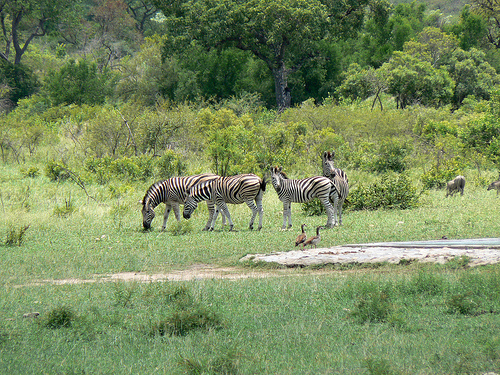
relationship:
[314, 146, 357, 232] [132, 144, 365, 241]
zebra in group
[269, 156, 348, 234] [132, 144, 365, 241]
zebra in group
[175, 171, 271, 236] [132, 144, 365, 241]
zebra in group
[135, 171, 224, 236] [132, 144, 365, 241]
zebra in group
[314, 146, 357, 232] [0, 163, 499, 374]
zebra in grass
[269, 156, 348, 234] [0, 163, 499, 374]
zebra in grass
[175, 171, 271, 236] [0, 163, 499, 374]
zebra in grass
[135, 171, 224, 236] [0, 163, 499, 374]
zebra in grass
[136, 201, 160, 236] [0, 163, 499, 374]
head touching grass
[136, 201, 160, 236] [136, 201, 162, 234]
head angled down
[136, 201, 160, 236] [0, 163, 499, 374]
head angled torward grass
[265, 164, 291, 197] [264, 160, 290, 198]
head turned to side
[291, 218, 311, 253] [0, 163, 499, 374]
bird in grass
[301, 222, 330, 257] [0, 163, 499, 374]
bird in grass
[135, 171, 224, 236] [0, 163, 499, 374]
zebra grazing grass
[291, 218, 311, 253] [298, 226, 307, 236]
bird has neck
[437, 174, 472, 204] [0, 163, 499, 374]
animal in grass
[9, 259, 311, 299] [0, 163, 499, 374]
sand beside grass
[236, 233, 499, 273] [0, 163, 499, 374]
pavement beside grass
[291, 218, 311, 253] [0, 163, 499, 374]
bird walking in grass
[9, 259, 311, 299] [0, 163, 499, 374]
sand in grass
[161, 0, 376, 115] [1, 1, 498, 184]
tree in brush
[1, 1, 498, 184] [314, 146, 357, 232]
brush behind zebra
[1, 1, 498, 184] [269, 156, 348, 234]
brush behind zebra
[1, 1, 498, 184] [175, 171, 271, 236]
brush behind zebra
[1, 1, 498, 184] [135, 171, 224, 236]
brush behind zebra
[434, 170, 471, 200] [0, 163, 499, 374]
zebra grazing in grass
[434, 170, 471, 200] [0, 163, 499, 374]
zebra in grass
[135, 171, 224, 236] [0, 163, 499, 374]
zebra grazing in grass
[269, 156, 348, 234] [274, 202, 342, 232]
zebra has legs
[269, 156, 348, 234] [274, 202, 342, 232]
zebra has four legs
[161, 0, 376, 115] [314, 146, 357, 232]
tree behind zebra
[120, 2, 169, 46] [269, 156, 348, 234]
tree behind zebra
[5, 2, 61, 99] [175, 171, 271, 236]
tree behind zebra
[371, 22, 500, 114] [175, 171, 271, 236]
tree behind zebra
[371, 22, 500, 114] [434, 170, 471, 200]
tree behind zebra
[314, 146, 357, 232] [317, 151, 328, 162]
zebra has ear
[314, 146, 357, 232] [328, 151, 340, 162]
zebra has ear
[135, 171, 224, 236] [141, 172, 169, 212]
zebra has hair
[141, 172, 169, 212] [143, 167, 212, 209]
hair on back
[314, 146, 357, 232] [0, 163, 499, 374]
zebra on grass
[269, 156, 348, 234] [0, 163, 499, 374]
zebra on grass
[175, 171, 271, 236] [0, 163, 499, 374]
zebra on grass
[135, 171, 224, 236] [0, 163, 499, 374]
zebra on grass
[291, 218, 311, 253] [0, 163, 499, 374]
bird on grass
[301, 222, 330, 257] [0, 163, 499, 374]
bird on grass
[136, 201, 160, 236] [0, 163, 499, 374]
head on grass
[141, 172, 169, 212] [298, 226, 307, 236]
hair along neck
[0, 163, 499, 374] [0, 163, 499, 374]
grass in grass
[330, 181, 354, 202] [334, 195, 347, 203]
tail has hair